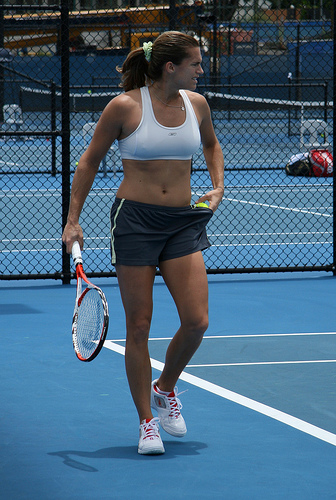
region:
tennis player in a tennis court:
[51, 19, 231, 468]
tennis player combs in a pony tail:
[85, 21, 237, 182]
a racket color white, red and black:
[58, 235, 115, 371]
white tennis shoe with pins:
[133, 374, 193, 469]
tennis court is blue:
[3, 275, 330, 498]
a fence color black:
[5, 11, 333, 285]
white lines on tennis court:
[96, 321, 335, 455]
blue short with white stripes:
[96, 197, 216, 267]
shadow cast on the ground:
[37, 424, 222, 486]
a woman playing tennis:
[61, 32, 225, 452]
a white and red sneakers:
[136, 378, 186, 453]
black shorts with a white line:
[110, 196, 211, 262]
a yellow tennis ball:
[195, 201, 207, 207]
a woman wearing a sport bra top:
[120, 86, 201, 160]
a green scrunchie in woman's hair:
[142, 40, 152, 60]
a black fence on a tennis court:
[1, 2, 335, 280]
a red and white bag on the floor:
[311, 147, 333, 177]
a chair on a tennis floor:
[4, 102, 24, 138]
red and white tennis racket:
[64, 243, 111, 361]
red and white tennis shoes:
[136, 415, 162, 453]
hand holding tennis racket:
[58, 219, 112, 362]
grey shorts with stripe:
[101, 196, 216, 262]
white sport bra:
[110, 84, 206, 164]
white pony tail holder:
[142, 38, 153, 62]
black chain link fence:
[248, 24, 286, 65]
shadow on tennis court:
[106, 448, 133, 456]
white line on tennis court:
[244, 398, 289, 426]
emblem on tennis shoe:
[154, 394, 166, 408]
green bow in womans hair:
[140, 38, 153, 61]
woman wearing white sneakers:
[136, 410, 163, 464]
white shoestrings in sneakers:
[147, 421, 159, 431]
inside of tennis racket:
[80, 318, 94, 335]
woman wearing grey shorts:
[136, 221, 152, 244]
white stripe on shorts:
[114, 203, 119, 225]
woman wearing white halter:
[151, 137, 163, 151]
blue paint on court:
[228, 444, 261, 475]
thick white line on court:
[270, 405, 307, 434]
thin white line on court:
[291, 354, 308, 370]